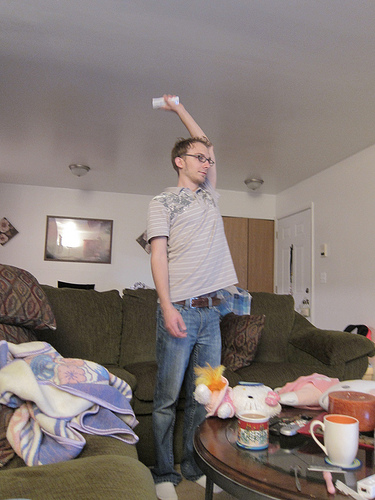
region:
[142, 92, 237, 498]
man standing with raised game controller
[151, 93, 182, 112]
white game controller in hand above man's head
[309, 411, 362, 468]
white mug on table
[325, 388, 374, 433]
orange candle on table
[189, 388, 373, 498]
brown circular table covered with items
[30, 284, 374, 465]
green comfortable looking couch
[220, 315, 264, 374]
brown pillow on couch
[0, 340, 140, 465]
purple, white, and pink blanket on couch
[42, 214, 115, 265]
brown framed picture on livingroom wall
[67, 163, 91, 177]
small white ceiling light in livingroom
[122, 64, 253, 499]
A man playing Wii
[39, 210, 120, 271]
A framed picture on the wall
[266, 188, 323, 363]
A white door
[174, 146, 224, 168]
Eye glasses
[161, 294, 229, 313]
A brown belt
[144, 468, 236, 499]
A pair of white socks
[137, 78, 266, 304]
A man holding a Wii controller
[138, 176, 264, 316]
A gray striped shirt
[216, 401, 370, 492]
Cups on the coffee table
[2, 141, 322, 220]
Light fixtures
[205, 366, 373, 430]
Two Hello Kitty dolls laying on coffee table.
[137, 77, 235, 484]
Man standing and holding game controller.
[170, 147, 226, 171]
Glasses on man's face.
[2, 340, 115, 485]
Blanket laying on couch.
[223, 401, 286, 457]
Cup of coffee sitting on table.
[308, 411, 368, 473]
White mug with an orange colored inside sitting on a coaster.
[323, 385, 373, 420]
Orange three wick candle.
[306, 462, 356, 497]
Pink handled dog brush.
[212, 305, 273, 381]
Throw pillow on couch.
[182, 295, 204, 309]
Belt buckle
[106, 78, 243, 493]
a young man holding a game controller over his head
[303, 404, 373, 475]
a large white coffee mug on a coffee table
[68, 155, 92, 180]
a light with a silver base in the ceiling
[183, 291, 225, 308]
a brown belt the man is wearing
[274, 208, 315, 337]
a white door in the back of the room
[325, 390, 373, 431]
a very large brown wax candle on the table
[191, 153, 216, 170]
wire-rimmed glasses the man is wearing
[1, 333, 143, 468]
a white, purple and pink blanket on a couch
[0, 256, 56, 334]
a dark patterned pillow on the couch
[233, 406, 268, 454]
a white, reg and green designed coffee mug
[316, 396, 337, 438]
White coffee mug on table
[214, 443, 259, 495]
Table has glass top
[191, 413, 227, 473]
Brown wood on coffee table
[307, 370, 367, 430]
Orange candle on table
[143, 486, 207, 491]
Man wearing white socks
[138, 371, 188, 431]
Man wearing blue jeans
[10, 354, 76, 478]
Blanket on couch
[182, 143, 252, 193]
Man is wearing glasses on face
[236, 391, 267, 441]
Red and mostly white coffee mug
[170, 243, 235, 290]
Man wearing gray and white striped shirt